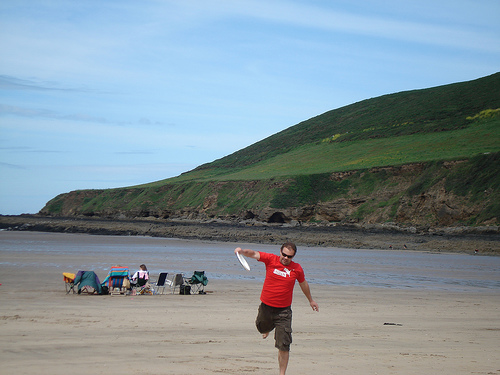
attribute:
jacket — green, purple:
[75, 271, 104, 293]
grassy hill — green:
[42, 68, 498, 233]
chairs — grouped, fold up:
[181, 266, 226, 313]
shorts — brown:
[256, 302, 292, 351]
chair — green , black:
[174, 264, 242, 289]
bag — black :
[159, 273, 197, 298]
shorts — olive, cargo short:
[232, 277, 300, 353]